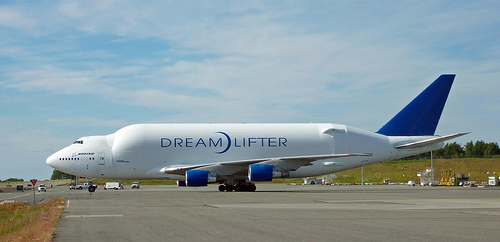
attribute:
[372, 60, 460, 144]
tail — blue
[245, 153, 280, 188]
engines — blue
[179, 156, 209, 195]
engines — blue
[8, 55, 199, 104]
cloud — white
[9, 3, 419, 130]
cloud — white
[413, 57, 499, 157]
cloud — white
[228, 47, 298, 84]
clouds — white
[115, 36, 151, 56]
sky — blue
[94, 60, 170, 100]
clouds — white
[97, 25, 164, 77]
sky — blue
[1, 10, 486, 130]
clouds — white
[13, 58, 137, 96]
cloud — white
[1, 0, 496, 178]
sky — blue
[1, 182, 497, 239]
runway — large, concrete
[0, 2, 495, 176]
clouds — white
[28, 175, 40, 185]
sign — red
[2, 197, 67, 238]
grass — green, brown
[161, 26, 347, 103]
cloud — white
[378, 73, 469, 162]
plane's tail — blue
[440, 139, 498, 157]
trees — tall, green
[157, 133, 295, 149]
name — blue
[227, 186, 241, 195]
wheel — black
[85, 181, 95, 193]
wheel — black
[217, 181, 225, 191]
wheel — black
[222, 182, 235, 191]
wheel — black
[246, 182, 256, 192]
wheel — black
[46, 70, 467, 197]
plane — white